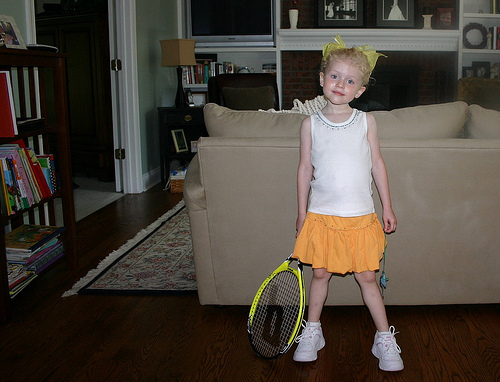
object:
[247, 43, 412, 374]
girl holding racket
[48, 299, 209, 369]
floor is hardwood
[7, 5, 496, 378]
livingroom has wood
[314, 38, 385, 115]
girl has bow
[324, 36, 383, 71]
bow in hair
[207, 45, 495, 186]
sofa faces brick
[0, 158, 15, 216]
books are upright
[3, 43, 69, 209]
shelf has books.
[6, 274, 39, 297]
books lay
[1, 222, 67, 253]
books on bottom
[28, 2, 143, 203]
door to other room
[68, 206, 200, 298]
floor has rug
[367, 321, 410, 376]
girl wears shoes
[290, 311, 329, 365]
girl wears socks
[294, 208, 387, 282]
girl wears skirt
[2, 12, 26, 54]
photo is framed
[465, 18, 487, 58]
wreath on shelf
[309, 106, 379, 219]
shirt is yellow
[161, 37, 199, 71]
shade is tan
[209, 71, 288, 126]
tv is large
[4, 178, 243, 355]
room has hardwood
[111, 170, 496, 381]
room has floors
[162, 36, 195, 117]
lamp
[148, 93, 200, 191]
table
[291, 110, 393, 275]
outfit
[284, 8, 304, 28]
vase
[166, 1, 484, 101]
mantel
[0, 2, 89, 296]
bookshelf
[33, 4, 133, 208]
doorway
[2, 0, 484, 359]
room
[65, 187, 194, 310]
floor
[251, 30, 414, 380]
girl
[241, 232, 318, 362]
racket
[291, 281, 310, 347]
rim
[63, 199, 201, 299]
rug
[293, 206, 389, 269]
skirt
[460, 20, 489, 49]
wreath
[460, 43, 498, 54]
shelf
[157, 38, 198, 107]
table lamp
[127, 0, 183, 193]
wall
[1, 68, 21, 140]
books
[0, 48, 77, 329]
shelf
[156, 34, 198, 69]
lamp shade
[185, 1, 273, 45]
television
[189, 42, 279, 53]
shelf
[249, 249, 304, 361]
tennis racket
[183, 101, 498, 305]
couch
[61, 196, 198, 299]
area rug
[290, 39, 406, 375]
she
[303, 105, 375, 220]
tank top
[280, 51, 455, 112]
fireplace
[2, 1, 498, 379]
living room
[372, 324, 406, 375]
shoe